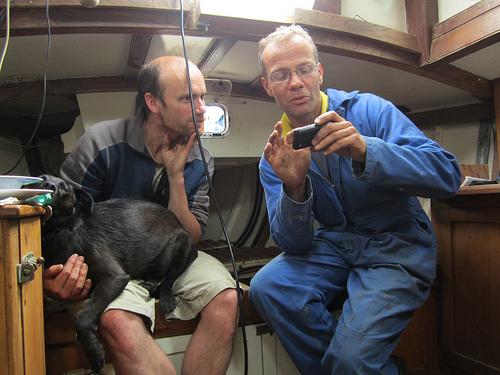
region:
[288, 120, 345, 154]
A small cell phone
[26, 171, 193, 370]
A black lab sitting in a man's lap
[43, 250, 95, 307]
A hand holding onto a dog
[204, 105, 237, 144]
Small window that is open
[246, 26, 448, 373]
Man wearing blue overalls.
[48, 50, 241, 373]
A man that is going bald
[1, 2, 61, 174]
Electric wires hanging down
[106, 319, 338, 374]
White cabinets for storage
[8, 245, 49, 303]
Lock on a wooden cabinet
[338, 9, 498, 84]
Wooden framing inside a boat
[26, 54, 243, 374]
man holding a sleeping black dog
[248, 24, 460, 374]
man in blue jump suit using black device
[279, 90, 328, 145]
yellow collar of an undershirt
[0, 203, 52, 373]
medium brown wood cabinet with tarnished brass lock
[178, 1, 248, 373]
black cord hanging from ceiling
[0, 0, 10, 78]
short white cord hanging from ceiling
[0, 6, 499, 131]
curved dark brown wooden rafters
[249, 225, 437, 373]
trouser portion of blue coveralls is dirty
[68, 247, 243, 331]
light khaki shorts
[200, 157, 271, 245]
dark shadowy passage way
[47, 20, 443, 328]
two men looking at one cellphone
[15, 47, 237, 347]
man holding black dog on lap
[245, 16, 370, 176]
man looking at phone in both hands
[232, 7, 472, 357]
man wearing blue jumpsuit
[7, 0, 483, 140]
curved ceiling with wooden supports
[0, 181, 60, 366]
wooden cabinet with metal latch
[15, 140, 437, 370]
bench on top of white cabinets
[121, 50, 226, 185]
man holding up chin with fingers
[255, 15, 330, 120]
man with wide forehead and eyeglasses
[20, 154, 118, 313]
hand curled up over sleeping dog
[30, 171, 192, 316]
black dog in man's lap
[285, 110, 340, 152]
Cellphone being held by man on right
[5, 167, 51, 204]
dishes sitting on cabinet on left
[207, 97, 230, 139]
window on wall behind men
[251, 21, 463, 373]
Man in blue jumpsuit on right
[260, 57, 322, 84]
glasses worn by man on right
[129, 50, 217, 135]
bald man on left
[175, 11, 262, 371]
cable wire hanging from roof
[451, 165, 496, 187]
papers laying on counter on right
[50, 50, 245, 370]
man on left wearing shorts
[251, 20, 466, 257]
a blue colour dressed man looking his mobile phone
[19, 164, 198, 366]
a black colour dog is sleeping in the man's lap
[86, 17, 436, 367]
both are looking at the mobile phone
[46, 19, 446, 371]
both the person are sitting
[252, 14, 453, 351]
a blue colour dressed man wearning eye glasses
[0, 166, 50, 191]
a cup above the cupboard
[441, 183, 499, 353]
a brown colour cupboard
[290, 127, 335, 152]
a black colour mobile phone in his hand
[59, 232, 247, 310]
a bald man wearing cream colour shorts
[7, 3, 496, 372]
a wooden furniture with many colours